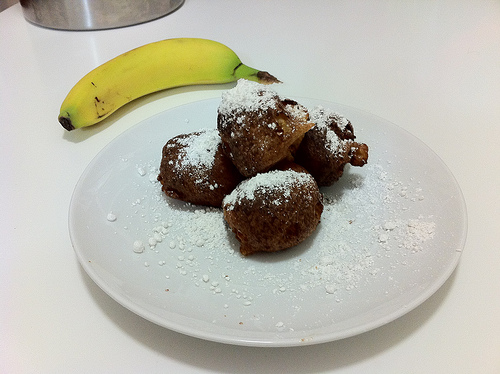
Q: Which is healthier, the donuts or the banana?
A: The banana is healthier than the donuts.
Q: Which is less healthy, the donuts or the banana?
A: The donuts is less healthy than the banana.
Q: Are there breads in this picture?
A: No, there are no breads.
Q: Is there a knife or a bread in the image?
A: No, there are no breads or knives.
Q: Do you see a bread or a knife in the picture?
A: No, there are no breads or knives.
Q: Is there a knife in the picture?
A: No, there are no knives.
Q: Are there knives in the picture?
A: No, there are no knives.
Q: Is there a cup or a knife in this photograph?
A: No, there are no knives or cups.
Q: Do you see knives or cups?
A: No, there are no knives or cups.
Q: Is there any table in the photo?
A: Yes, there is a table.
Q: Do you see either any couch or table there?
A: Yes, there is a table.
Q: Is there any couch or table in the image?
A: Yes, there is a table.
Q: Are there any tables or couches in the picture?
A: Yes, there is a table.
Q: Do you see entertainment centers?
A: No, there are no entertainment centers.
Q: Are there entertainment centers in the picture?
A: No, there are no entertainment centers.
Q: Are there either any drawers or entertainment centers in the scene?
A: No, there are no entertainment centers or drawers.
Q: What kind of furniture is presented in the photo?
A: The furniture is a table.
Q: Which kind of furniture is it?
A: The piece of furniture is a table.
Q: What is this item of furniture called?
A: This is a table.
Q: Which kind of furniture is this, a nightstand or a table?
A: This is a table.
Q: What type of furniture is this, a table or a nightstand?
A: This is a table.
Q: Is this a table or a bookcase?
A: This is a table.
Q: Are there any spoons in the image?
A: No, there are no spoons.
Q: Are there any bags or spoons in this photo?
A: No, there are no spoons or bags.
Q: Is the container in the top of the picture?
A: Yes, the container is in the top of the image.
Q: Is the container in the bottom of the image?
A: No, the container is in the top of the image.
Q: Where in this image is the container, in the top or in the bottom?
A: The container is in the top of the image.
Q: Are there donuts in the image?
A: Yes, there are donuts.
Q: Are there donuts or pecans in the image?
A: Yes, there are donuts.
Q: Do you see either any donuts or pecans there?
A: Yes, there are donuts.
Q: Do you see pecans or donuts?
A: Yes, there are donuts.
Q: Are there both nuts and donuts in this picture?
A: No, there are donuts but no nuts.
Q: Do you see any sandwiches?
A: No, there are no sandwiches.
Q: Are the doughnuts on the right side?
A: Yes, the doughnuts are on the right of the image.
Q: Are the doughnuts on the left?
A: No, the doughnuts are on the right of the image.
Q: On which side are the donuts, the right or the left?
A: The donuts are on the right of the image.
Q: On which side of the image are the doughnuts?
A: The doughnuts are on the right of the image.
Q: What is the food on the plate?
A: The food is donuts.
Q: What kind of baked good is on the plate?
A: The food is donuts.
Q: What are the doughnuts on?
A: The doughnuts are on the plate.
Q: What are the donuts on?
A: The doughnuts are on the plate.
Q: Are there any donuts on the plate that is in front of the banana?
A: Yes, there are donuts on the plate.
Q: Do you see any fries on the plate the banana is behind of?
A: No, there are donuts on the plate.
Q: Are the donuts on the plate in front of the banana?
A: Yes, the donuts are on the plate.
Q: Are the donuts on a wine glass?
A: No, the donuts are on the plate.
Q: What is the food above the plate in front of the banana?
A: The food is donuts.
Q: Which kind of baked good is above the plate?
A: The food is donuts.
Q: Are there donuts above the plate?
A: Yes, there are donuts above the plate.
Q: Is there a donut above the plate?
A: Yes, there are donuts above the plate.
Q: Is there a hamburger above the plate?
A: No, there are donuts above the plate.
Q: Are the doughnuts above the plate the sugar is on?
A: Yes, the doughnuts are above the plate.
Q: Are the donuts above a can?
A: No, the donuts are above the plate.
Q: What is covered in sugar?
A: The donuts are covered in sugar.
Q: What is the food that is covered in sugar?
A: The food is donuts.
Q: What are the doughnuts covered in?
A: The doughnuts are covered in sugar.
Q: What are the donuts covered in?
A: The doughnuts are covered in sugar.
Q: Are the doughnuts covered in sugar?
A: Yes, the doughnuts are covered in sugar.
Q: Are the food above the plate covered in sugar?
A: Yes, the doughnuts are covered in sugar.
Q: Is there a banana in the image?
A: Yes, there is a banana.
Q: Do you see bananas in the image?
A: Yes, there is a banana.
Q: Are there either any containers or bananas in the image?
A: Yes, there is a banana.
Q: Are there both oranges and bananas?
A: No, there is a banana but no oranges.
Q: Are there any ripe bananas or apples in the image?
A: Yes, there is a ripe banana.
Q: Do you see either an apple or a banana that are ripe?
A: Yes, the banana is ripe.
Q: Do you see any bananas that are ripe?
A: Yes, there is a ripe banana.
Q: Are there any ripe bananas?
A: Yes, there is a ripe banana.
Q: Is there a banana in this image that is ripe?
A: Yes, there is a banana that is ripe.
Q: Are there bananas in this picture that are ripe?
A: Yes, there is a banana that is ripe.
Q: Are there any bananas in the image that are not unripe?
A: Yes, there is an ripe banana.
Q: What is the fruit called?
A: The fruit is a banana.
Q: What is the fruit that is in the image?
A: The fruit is a banana.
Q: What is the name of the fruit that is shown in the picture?
A: The fruit is a banana.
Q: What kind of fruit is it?
A: The fruit is a banana.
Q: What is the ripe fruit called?
A: The fruit is a banana.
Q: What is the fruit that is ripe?
A: The fruit is a banana.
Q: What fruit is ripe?
A: The fruit is a banana.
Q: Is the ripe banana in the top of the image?
A: Yes, the banana is in the top of the image.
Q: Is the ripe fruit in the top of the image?
A: Yes, the banana is in the top of the image.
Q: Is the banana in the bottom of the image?
A: No, the banana is in the top of the image.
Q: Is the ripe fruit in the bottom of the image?
A: No, the banana is in the top of the image.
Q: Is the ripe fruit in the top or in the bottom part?
A: The banana is in the top of the image.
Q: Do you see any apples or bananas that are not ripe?
A: No, there is a banana but it is ripe.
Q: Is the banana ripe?
A: Yes, the banana is ripe.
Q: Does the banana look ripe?
A: Yes, the banana is ripe.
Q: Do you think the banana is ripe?
A: Yes, the banana is ripe.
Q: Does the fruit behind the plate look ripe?
A: Yes, the banana is ripe.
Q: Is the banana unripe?
A: No, the banana is ripe.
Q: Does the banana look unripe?
A: No, the banana is ripe.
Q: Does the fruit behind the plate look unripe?
A: No, the banana is ripe.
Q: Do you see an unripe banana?
A: No, there is a banana but it is ripe.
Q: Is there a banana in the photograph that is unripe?
A: No, there is a banana but it is ripe.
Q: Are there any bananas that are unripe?
A: No, there is a banana but it is ripe.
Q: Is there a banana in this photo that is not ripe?
A: No, there is a banana but it is ripe.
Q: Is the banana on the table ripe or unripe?
A: The banana is ripe.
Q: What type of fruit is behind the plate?
A: The fruit is a banana.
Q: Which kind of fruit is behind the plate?
A: The fruit is a banana.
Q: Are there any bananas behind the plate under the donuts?
A: Yes, there is a banana behind the plate.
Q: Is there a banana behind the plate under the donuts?
A: Yes, there is a banana behind the plate.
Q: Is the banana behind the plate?
A: Yes, the banana is behind the plate.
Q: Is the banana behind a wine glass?
A: No, the banana is behind the plate.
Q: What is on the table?
A: The banana is on the table.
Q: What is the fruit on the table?
A: The fruit is a banana.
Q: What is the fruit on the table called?
A: The fruit is a banana.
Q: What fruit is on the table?
A: The fruit is a banana.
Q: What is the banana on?
A: The banana is on the table.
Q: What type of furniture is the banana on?
A: The banana is on the table.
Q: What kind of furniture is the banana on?
A: The banana is on the table.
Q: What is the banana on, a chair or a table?
A: The banana is on a table.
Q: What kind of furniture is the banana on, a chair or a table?
A: The banana is on a table.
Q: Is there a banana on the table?
A: Yes, there is a banana on the table.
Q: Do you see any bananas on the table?
A: Yes, there is a banana on the table.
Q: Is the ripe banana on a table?
A: Yes, the banana is on a table.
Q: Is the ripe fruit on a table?
A: Yes, the banana is on a table.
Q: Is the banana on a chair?
A: No, the banana is on a table.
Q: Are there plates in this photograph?
A: Yes, there is a plate.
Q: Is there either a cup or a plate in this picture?
A: Yes, there is a plate.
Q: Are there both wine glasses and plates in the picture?
A: No, there is a plate but no wine glasses.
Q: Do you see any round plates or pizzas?
A: Yes, there is a round plate.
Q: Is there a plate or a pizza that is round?
A: Yes, the plate is round.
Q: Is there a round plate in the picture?
A: Yes, there is a round plate.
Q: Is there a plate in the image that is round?
A: Yes, there is a round plate.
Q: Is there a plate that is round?
A: Yes, there is a plate that is round.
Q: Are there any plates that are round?
A: Yes, there is a plate that is round.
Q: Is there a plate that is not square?
A: Yes, there is a round plate.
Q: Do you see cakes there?
A: No, there are no cakes.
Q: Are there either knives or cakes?
A: No, there are no cakes or knives.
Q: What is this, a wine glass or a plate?
A: This is a plate.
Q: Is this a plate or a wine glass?
A: This is a plate.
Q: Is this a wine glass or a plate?
A: This is a plate.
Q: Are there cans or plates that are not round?
A: No, there is a plate but it is round.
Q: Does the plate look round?
A: Yes, the plate is round.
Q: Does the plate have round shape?
A: Yes, the plate is round.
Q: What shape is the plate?
A: The plate is round.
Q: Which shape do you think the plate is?
A: The plate is round.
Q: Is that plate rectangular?
A: No, the plate is round.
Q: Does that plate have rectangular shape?
A: No, the plate is round.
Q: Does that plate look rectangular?
A: No, the plate is round.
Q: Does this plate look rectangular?
A: No, the plate is round.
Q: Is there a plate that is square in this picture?
A: No, there is a plate but it is round.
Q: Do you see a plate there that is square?
A: No, there is a plate but it is round.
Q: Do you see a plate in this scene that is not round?
A: No, there is a plate but it is round.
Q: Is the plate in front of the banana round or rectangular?
A: The plate is round.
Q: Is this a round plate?
A: Yes, this is a round plate.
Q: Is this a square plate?
A: No, this is a round plate.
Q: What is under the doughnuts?
A: The plate is under the doughnuts.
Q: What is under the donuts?
A: The plate is under the doughnuts.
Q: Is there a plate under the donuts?
A: Yes, there is a plate under the donuts.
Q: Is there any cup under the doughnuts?
A: No, there is a plate under the doughnuts.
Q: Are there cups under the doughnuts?
A: No, there is a plate under the doughnuts.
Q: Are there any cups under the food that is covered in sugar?
A: No, there is a plate under the doughnuts.